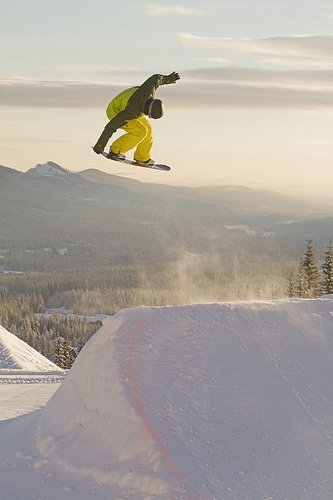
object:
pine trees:
[284, 241, 332, 303]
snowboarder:
[92, 66, 180, 168]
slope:
[1, 314, 64, 374]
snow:
[1, 299, 332, 499]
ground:
[0, 367, 89, 499]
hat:
[147, 97, 161, 117]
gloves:
[164, 68, 186, 89]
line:
[1, 363, 67, 382]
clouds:
[226, 23, 332, 64]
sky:
[2, 2, 332, 213]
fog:
[0, 119, 332, 227]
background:
[0, 0, 331, 304]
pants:
[109, 116, 152, 168]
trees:
[0, 230, 332, 364]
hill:
[0, 158, 332, 284]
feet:
[103, 144, 154, 166]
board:
[74, 140, 172, 173]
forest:
[0, 228, 332, 369]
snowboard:
[101, 148, 171, 172]